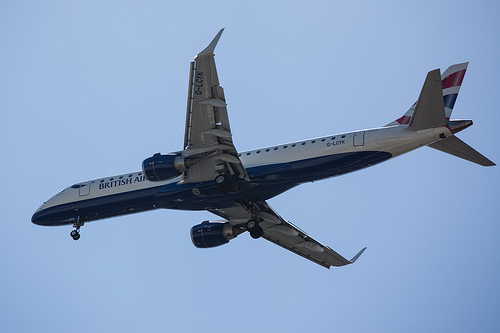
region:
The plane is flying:
[18, 18, 493, 285]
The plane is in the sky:
[27, 29, 494, 286]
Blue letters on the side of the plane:
[93, 174, 167, 195]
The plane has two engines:
[131, 147, 273, 247]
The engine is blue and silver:
[141, 141, 206, 181]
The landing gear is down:
[56, 168, 278, 245]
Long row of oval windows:
[90, 126, 351, 191]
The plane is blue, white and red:
[30, 32, 489, 282]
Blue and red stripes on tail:
[388, 54, 483, 134]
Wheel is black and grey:
[207, 167, 240, 198]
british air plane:
[25, 25, 496, 326]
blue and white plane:
[37, 16, 497, 269]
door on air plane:
[70, 175, 100, 200]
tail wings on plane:
[395, 61, 495, 181]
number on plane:
[190, 70, 215, 95]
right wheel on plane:
[245, 215, 260, 245]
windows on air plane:
[245, 130, 355, 160]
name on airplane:
[95, 170, 151, 186]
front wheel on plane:
[61, 227, 81, 248]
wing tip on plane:
[344, 242, 371, 273]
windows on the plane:
[87, 170, 145, 186]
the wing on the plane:
[187, 26, 229, 141]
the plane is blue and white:
[25, 38, 484, 277]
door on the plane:
[351, 130, 368, 147]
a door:
[75, 181, 86, 198]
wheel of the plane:
[248, 225, 263, 240]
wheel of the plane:
[211, 170, 233, 190]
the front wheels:
[64, 229, 83, 242]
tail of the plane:
[444, 62, 465, 122]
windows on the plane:
[257, 140, 316, 153]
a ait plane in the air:
[22, 29, 499, 296]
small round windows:
[249, 134, 356, 159]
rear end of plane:
[394, 59, 499, 174]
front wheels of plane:
[70, 226, 83, 244]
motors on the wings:
[138, 151, 201, 185]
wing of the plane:
[206, 209, 393, 277]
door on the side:
[74, 176, 94, 202]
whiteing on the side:
[97, 171, 148, 193]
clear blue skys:
[28, 2, 160, 120]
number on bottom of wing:
[188, 64, 220, 108]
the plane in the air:
[12, 21, 494, 276]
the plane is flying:
[30, 20, 495, 276]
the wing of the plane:
[120, 26, 276, 178]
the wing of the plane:
[187, 207, 372, 274]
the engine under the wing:
[136, 145, 207, 184]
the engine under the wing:
[190, 210, 252, 256]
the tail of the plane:
[378, 45, 499, 173]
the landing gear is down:
[46, 160, 289, 267]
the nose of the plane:
[22, 192, 58, 239]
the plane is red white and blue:
[4, 25, 461, 315]